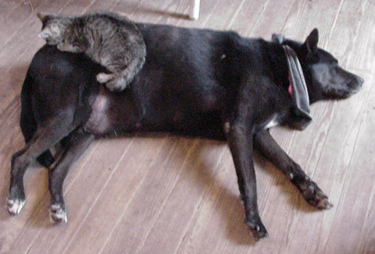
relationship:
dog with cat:
[0, 8, 363, 239] [30, 7, 149, 98]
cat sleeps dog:
[30, 7, 149, 98] [0, 8, 363, 239]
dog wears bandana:
[0, 8, 363, 239] [268, 30, 321, 132]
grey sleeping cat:
[52, 21, 128, 51] [30, 7, 149, 98]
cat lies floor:
[30, 7, 149, 98] [4, 9, 23, 102]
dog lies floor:
[0, 8, 363, 239] [4, 9, 23, 102]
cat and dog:
[30, 7, 149, 98] [0, 8, 363, 239]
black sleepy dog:
[163, 37, 248, 96] [0, 8, 363, 239]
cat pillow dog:
[30, 7, 149, 98] [0, 8, 363, 239]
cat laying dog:
[30, 7, 149, 98] [0, 8, 363, 239]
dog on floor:
[0, 8, 363, 239] [4, 9, 23, 102]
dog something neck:
[0, 8, 363, 239] [272, 29, 294, 117]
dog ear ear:
[0, 8, 363, 239] [298, 28, 320, 59]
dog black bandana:
[0, 8, 363, 239] [268, 30, 321, 132]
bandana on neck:
[268, 30, 321, 132] [272, 29, 294, 117]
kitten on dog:
[30, 7, 149, 98] [0, 8, 363, 239]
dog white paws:
[0, 8, 363, 239] [2, 196, 85, 226]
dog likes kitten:
[15, 8, 363, 185] [30, 7, 149, 98]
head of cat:
[35, 5, 77, 51] [30, 7, 149, 98]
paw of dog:
[306, 186, 334, 215] [15, 8, 363, 185]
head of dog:
[291, 19, 367, 128] [15, 8, 363, 185]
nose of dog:
[350, 71, 371, 96] [15, 8, 363, 185]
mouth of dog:
[319, 81, 362, 100] [15, 8, 363, 185]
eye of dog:
[329, 57, 340, 72] [15, 8, 363, 185]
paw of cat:
[90, 69, 109, 88] [30, 7, 149, 98]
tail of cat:
[110, 54, 148, 101] [30, 7, 149, 98]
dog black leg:
[15, 8, 363, 185] [223, 113, 268, 218]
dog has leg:
[15, 8, 363, 185] [223, 113, 268, 218]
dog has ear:
[15, 8, 363, 185] [298, 23, 324, 58]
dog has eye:
[15, 8, 363, 185] [329, 57, 340, 72]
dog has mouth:
[15, 8, 363, 185] [319, 81, 362, 100]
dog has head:
[15, 8, 363, 185] [291, 19, 367, 128]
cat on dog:
[30, 7, 149, 98] [15, 8, 363, 185]